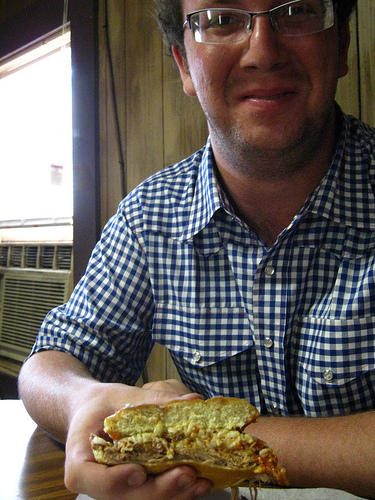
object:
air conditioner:
[0, 226, 73, 380]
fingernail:
[178, 473, 194, 489]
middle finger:
[122, 464, 199, 499]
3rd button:
[264, 337, 273, 349]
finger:
[64, 455, 146, 499]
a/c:
[0, 225, 75, 380]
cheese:
[227, 430, 290, 499]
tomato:
[252, 438, 291, 487]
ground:
[297, 122, 336, 178]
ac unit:
[0, 239, 74, 378]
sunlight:
[0, 22, 75, 244]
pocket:
[150, 298, 261, 413]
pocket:
[294, 313, 374, 418]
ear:
[172, 41, 197, 96]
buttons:
[265, 265, 275, 275]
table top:
[0, 397, 371, 498]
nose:
[239, 8, 290, 72]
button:
[323, 369, 334, 381]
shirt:
[22, 114, 374, 419]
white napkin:
[218, 487, 368, 499]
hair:
[151, 0, 183, 56]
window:
[0, 27, 74, 249]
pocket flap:
[150, 303, 253, 369]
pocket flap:
[296, 316, 374, 385]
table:
[0, 401, 375, 500]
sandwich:
[88, 396, 290, 500]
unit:
[0, 240, 75, 383]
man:
[17, 0, 375, 499]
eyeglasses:
[175, 0, 347, 47]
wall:
[0, 0, 375, 389]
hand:
[63, 378, 216, 499]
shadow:
[17, 423, 76, 498]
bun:
[102, 396, 259, 439]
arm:
[275, 413, 375, 496]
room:
[0, 0, 375, 499]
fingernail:
[125, 467, 148, 488]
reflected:
[0, 400, 39, 499]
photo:
[0, 0, 374, 495]